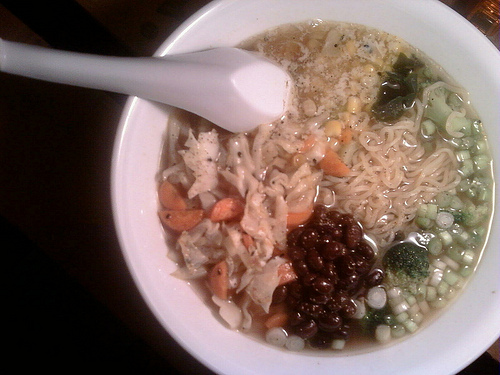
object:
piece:
[156, 209, 203, 228]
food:
[203, 192, 251, 224]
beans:
[286, 209, 371, 336]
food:
[282, 189, 387, 367]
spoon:
[0, 39, 292, 134]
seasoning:
[185, 127, 230, 191]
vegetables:
[172, 123, 372, 308]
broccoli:
[387, 222, 447, 295]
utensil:
[3, 37, 293, 132]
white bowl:
[99, 2, 499, 373]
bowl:
[110, 1, 498, 372]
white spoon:
[22, 41, 297, 117]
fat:
[327, 71, 362, 88]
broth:
[303, 26, 346, 51]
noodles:
[317, 79, 441, 234]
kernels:
[312, 93, 372, 158]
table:
[0, 1, 498, 373]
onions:
[439, 210, 469, 259]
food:
[144, 32, 496, 349]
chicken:
[190, 206, 288, 319]